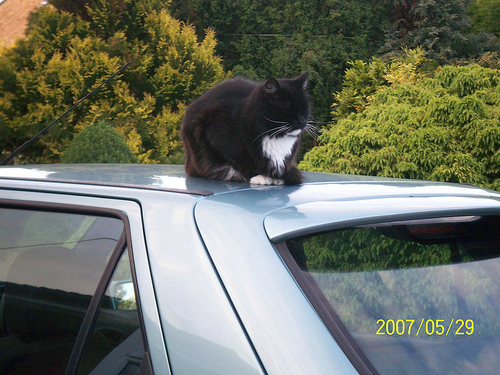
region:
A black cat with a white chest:
[180, 79, 310, 185]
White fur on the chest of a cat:
[263, 133, 300, 171]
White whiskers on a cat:
[302, 120, 323, 137]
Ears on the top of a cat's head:
[262, 68, 312, 92]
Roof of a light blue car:
[1, 162, 498, 264]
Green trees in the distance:
[1, 1, 498, 168]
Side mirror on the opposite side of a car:
[111, 282, 138, 312]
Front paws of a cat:
[253, 171, 287, 186]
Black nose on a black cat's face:
[298, 121, 305, 127]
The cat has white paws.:
[240, 165, 296, 190]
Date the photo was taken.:
[372, 314, 482, 339]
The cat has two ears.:
[260, 61, 316, 105]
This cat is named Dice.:
[173, 55, 329, 196]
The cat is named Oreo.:
[179, 48, 334, 193]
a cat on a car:
[132, 82, 434, 259]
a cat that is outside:
[199, 62, 324, 208]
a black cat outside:
[147, 30, 327, 257]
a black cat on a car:
[193, 86, 340, 230]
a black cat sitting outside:
[136, 37, 350, 214]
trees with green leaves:
[336, 44, 499, 181]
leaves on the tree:
[289, 33, 487, 158]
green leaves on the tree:
[387, 61, 493, 147]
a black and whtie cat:
[158, 58, 489, 339]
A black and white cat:
[179, 69, 325, 181]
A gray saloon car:
[0, 60, 499, 374]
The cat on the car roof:
[2, 63, 499, 373]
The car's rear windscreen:
[278, 212, 498, 374]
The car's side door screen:
[0, 190, 150, 374]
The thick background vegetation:
[0, 0, 498, 190]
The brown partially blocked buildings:
[0, 0, 50, 52]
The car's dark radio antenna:
[1, 61, 134, 168]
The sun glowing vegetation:
[0, 0, 499, 194]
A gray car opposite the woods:
[0, 0, 498, 373]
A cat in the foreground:
[173, 59, 325, 194]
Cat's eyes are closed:
[255, 67, 327, 147]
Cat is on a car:
[1, 53, 497, 373]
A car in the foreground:
[3, 157, 499, 374]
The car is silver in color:
[1, 149, 498, 372]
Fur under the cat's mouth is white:
[256, 120, 303, 175]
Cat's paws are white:
[243, 167, 292, 195]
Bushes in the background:
[1, 4, 499, 336]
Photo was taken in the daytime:
[2, 0, 493, 373]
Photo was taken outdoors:
[3, 2, 498, 370]